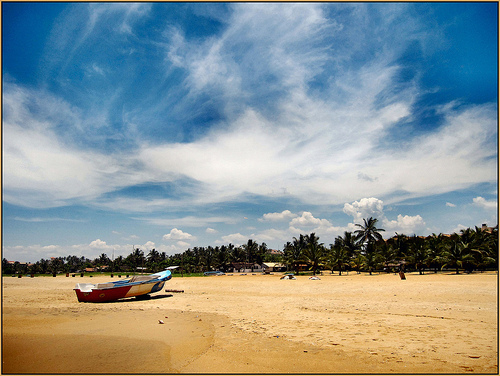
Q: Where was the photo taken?
A: It was taken at the beach.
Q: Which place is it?
A: It is a beach.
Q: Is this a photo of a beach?
A: Yes, it is showing a beach.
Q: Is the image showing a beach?
A: Yes, it is showing a beach.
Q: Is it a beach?
A: Yes, it is a beach.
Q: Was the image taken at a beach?
A: Yes, it was taken in a beach.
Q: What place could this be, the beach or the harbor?
A: It is the beach.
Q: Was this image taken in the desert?
A: No, the picture was taken in the beach.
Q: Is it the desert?
A: No, it is the beach.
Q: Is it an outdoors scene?
A: Yes, it is outdoors.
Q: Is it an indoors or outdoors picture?
A: It is outdoors.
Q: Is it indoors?
A: No, it is outdoors.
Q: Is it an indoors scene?
A: No, it is outdoors.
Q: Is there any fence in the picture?
A: No, there are no fences.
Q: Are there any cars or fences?
A: No, there are no fences or cars.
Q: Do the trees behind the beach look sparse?
A: No, the trees are dense.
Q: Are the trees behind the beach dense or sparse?
A: The trees are dense.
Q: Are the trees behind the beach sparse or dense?
A: The trees are dense.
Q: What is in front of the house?
A: The trees are in front of the house.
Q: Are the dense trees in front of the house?
A: Yes, the trees are in front of the house.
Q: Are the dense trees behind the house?
A: No, the trees are in front of the house.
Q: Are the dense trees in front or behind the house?
A: The trees are in front of the house.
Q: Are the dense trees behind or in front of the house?
A: The trees are in front of the house.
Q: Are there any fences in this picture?
A: No, there are no fences.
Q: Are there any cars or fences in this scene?
A: No, there are no fences or cars.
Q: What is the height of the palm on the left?
A: The palm is tall.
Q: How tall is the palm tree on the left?
A: The palm is tall.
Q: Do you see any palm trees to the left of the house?
A: Yes, there is a palm tree to the left of the house.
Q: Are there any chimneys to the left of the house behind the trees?
A: No, there is a palm tree to the left of the house.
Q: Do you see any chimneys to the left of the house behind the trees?
A: No, there is a palm tree to the left of the house.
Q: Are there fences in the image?
A: No, there are no fences.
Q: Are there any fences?
A: No, there are no fences.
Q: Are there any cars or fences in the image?
A: No, there are no fences or cars.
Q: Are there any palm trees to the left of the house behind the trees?
A: Yes, there is a palm tree to the left of the house.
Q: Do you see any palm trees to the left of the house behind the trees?
A: Yes, there is a palm tree to the left of the house.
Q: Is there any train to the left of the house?
A: No, there is a palm tree to the left of the house.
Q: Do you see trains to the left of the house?
A: No, there is a palm tree to the left of the house.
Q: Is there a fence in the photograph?
A: No, there are no fences.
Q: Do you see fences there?
A: No, there are no fences.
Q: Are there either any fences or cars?
A: No, there are no fences or cars.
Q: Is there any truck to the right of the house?
A: No, there is a palm tree to the right of the house.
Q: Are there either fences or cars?
A: No, there are no fences or cars.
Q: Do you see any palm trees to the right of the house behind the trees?
A: Yes, there is a palm tree to the right of the house.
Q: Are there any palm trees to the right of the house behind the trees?
A: Yes, there is a palm tree to the right of the house.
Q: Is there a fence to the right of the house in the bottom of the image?
A: No, there is a palm tree to the right of the house.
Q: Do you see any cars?
A: No, there are no cars.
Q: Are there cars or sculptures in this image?
A: No, there are no cars or sculptures.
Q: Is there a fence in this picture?
A: No, there are no fences.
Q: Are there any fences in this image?
A: No, there are no fences.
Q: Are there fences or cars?
A: No, there are no fences or cars.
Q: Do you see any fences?
A: No, there are no fences.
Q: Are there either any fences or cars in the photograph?
A: No, there are no fences or cars.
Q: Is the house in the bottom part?
A: Yes, the house is in the bottom of the image.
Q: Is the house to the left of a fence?
A: No, the house is to the left of a palm tree.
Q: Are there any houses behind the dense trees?
A: Yes, there is a house behind the trees.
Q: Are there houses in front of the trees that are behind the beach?
A: No, the house is behind the trees.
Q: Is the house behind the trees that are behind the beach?
A: Yes, the house is behind the trees.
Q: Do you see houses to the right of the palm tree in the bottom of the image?
A: Yes, there is a house to the right of the palm.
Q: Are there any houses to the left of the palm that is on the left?
A: No, the house is to the right of the palm tree.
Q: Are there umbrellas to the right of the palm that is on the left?
A: No, there is a house to the right of the palm tree.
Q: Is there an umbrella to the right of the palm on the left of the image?
A: No, there is a house to the right of the palm tree.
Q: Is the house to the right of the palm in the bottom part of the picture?
A: Yes, the house is to the right of the palm.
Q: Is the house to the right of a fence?
A: No, the house is to the right of the palm.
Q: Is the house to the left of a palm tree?
A: Yes, the house is to the left of a palm tree.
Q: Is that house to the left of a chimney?
A: No, the house is to the left of a palm tree.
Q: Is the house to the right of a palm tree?
A: No, the house is to the left of a palm tree.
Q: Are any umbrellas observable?
A: No, there are no umbrellas.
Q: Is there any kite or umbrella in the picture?
A: No, there are no umbrellas or kites.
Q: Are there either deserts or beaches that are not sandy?
A: No, there is a beach but it is sandy.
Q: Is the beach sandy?
A: Yes, the beach is sandy.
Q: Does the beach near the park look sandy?
A: Yes, the beach is sandy.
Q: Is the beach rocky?
A: No, the beach is sandy.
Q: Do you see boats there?
A: Yes, there is a boat.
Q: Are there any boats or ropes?
A: Yes, there is a boat.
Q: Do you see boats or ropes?
A: Yes, there is a boat.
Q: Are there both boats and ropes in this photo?
A: No, there is a boat but no ropes.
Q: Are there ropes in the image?
A: No, there are no ropes.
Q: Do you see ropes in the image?
A: No, there are no ropes.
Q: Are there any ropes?
A: No, there are no ropes.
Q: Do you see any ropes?
A: No, there are no ropes.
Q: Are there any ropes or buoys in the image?
A: No, there are no ropes or buoys.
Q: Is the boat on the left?
A: Yes, the boat is on the left of the image.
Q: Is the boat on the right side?
A: No, the boat is on the left of the image.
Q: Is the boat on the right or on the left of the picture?
A: The boat is on the left of the image.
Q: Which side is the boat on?
A: The boat is on the left of the image.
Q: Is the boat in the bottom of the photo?
A: Yes, the boat is in the bottom of the image.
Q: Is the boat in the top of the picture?
A: No, the boat is in the bottom of the image.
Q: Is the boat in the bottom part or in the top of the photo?
A: The boat is in the bottom of the image.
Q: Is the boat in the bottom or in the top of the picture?
A: The boat is in the bottom of the image.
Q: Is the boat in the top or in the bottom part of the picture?
A: The boat is in the bottom of the image.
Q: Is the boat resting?
A: Yes, the boat is resting.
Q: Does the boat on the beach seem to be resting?
A: Yes, the boat is resting.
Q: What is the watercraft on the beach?
A: The watercraft is a boat.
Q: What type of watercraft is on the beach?
A: The watercraft is a boat.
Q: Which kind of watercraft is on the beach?
A: The watercraft is a boat.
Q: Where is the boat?
A: The boat is on the beach.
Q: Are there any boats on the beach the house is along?
A: Yes, there is a boat on the beach.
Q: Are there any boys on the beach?
A: No, there is a boat on the beach.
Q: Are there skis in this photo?
A: No, there are no skis.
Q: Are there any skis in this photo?
A: No, there are no skis.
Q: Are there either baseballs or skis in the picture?
A: No, there are no skis or baseballs.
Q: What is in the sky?
A: The clouds are in the sky.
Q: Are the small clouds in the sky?
A: Yes, the clouds are in the sky.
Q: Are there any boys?
A: No, there are no boys.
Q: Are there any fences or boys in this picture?
A: No, there are no boys or fences.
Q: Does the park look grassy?
A: Yes, the park is grassy.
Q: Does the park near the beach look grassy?
A: Yes, the park is grassy.